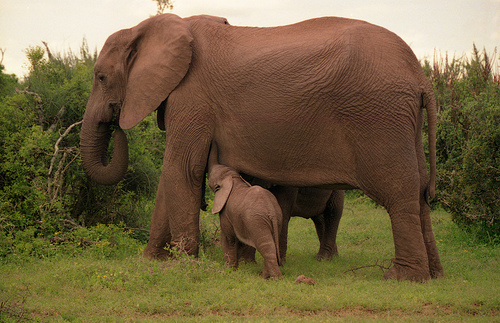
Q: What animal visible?
A: Elephant.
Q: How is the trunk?
A: Curled.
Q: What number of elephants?
A: Two.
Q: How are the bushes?
A: Leafy.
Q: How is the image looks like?
A: Good.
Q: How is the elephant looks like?
A: Heavy.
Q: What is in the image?
A: Elephants.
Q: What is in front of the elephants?
A: Trees.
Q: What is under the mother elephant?
A: Baby.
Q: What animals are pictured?
A: Elephants.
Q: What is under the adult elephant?
A: Young elephants.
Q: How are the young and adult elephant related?
A: Mother and child.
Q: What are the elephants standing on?
A: Grass.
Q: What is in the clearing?
A: Elephants.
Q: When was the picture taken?
A: At daytime.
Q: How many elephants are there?
A: Three.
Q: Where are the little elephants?
A: Under the mother's belly.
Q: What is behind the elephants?
A: Shrubs.